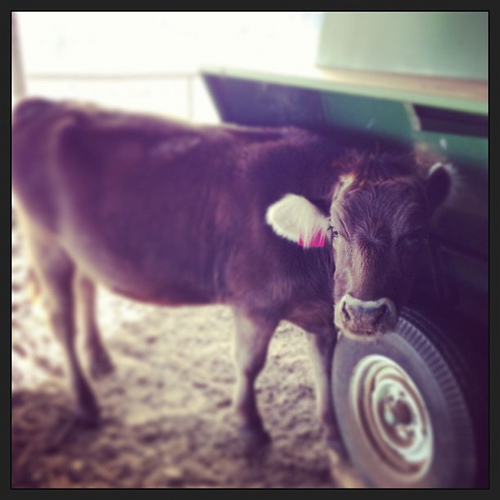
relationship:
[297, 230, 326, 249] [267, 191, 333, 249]
tag on ear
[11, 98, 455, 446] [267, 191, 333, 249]
cow has ear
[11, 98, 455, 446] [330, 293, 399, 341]
cow has snout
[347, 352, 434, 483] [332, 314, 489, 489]
metal on tire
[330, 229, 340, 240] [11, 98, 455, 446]
eye on cow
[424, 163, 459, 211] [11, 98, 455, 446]
ear on cow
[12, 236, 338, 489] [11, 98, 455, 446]
dirt under cow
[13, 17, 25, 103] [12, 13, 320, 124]
pane on window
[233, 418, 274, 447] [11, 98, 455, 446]
hoof of cow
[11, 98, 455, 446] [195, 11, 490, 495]
cow next to truck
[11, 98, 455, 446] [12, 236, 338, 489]
cow in dirt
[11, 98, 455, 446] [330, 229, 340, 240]
cow has eye